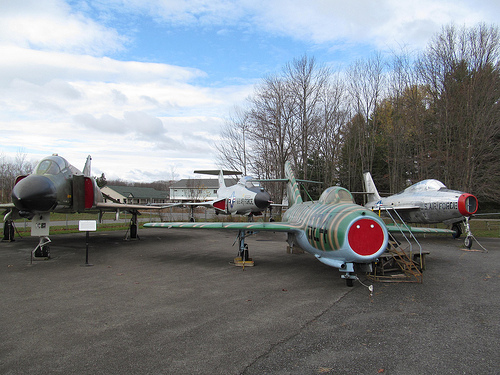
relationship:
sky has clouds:
[176, 22, 226, 71] [291, 13, 348, 46]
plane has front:
[292, 191, 410, 274] [341, 217, 391, 253]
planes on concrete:
[20, 136, 481, 289] [22, 314, 186, 351]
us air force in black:
[227, 194, 258, 207] [257, 195, 268, 204]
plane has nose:
[12, 154, 110, 207] [10, 185, 51, 210]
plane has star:
[172, 153, 271, 207] [225, 190, 246, 195]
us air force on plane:
[227, 194, 258, 207] [172, 153, 271, 207]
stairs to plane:
[356, 199, 435, 277] [292, 191, 410, 274]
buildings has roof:
[113, 174, 217, 207] [111, 185, 155, 199]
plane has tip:
[292, 191, 410, 274] [341, 217, 391, 253]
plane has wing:
[292, 191, 410, 274] [142, 219, 308, 241]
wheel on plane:
[334, 270, 364, 295] [292, 191, 410, 274]